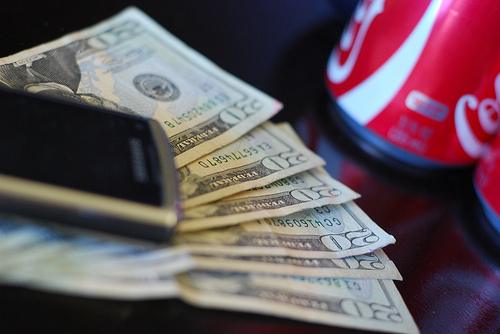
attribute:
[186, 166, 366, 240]
dollar — twenty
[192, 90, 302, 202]
bill — twenty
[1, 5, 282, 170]
dollar — twenty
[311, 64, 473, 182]
coke can — Coca Cola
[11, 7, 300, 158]
dollar bill — 20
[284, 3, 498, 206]
can — soda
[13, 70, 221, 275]
cell phone — turned off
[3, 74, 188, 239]
phone — black , silver 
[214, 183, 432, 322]
20 — dollar bill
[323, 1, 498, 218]
can — Coca Cola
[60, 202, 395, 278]
bill — twenty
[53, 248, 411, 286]
bill — twenty dollar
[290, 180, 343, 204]
"twenty" — green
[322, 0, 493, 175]
soda can — red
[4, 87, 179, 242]
cell phone — black, silver